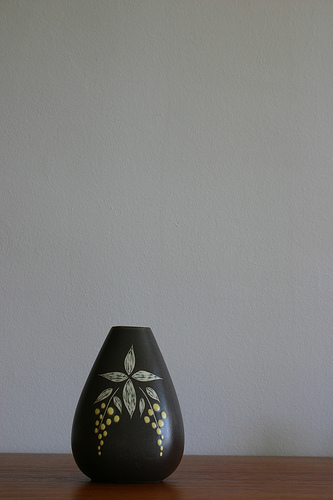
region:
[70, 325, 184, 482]
dark brown vase with stylized grapes design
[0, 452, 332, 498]
medium brown flat wooden surface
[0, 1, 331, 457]
plain dull grey wall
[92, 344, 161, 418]
leaf portion of design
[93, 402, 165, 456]
grapes portion of design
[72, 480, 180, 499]
dark brown shadow is cast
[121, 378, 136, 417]
large stylized grape leaf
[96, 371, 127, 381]
medium stylized grape leaf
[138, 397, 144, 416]
small stylized grape leaf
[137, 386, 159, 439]
long thing light grey grape stem drawing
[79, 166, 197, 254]
the wall is white in colour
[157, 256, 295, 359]
the wall has a rough texture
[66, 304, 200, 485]
a jar is on the table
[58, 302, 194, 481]
it is black in colour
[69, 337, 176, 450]
it has patterns on it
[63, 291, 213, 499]
it is on the table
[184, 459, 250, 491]
the table is wooden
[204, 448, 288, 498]
the table is brown in colour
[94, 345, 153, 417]
the patterns are of flowers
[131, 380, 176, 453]
it is yellow in colour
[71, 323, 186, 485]
vase is chocolate colored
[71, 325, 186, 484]
single vase that is empty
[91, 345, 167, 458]
hand painted flowers on vase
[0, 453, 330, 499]
wood furniture under vase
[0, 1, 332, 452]
long white wall behind vase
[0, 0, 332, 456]
wall is empty behind vase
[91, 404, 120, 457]
left side of white grapes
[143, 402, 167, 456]
right side of white grapes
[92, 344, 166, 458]
flower has two vines hanging from it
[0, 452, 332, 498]
wood has cherry finish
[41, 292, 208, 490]
vase on a table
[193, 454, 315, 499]
brown wooden table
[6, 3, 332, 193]
a white plaster wall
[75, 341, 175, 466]
painted docorations on a vase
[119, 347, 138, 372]
green petal painted on a vase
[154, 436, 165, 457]
round,yellow dots on a vase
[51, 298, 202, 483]
teardrop shaped black vase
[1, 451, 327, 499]
wooden table surface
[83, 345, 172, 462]
vase with a decorative deisgn on it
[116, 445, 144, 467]
black surface of a vase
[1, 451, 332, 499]
a brown wooden table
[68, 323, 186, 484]
a black oval vase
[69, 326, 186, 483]
a black vase with a plant painted on it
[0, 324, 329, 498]
a black vase on a table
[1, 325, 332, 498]
a black pained vase on a wooden table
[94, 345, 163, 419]
leaves pained on a vase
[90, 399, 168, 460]
yellow dots pained on a vase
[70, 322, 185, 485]
a teardrop shaped vase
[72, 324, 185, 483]
black vase in a teardrop shape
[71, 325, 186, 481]
front side of a pained vase